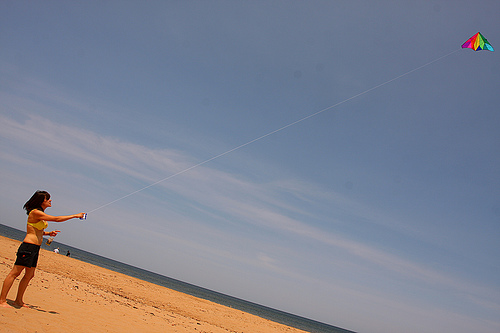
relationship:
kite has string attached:
[460, 30, 495, 58] [86, 44, 460, 206]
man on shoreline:
[53, 243, 61, 255] [73, 247, 312, 332]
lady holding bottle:
[0, 190, 87, 309] [45, 225, 59, 248]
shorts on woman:
[14, 241, 40, 266] [0, 190, 87, 309]